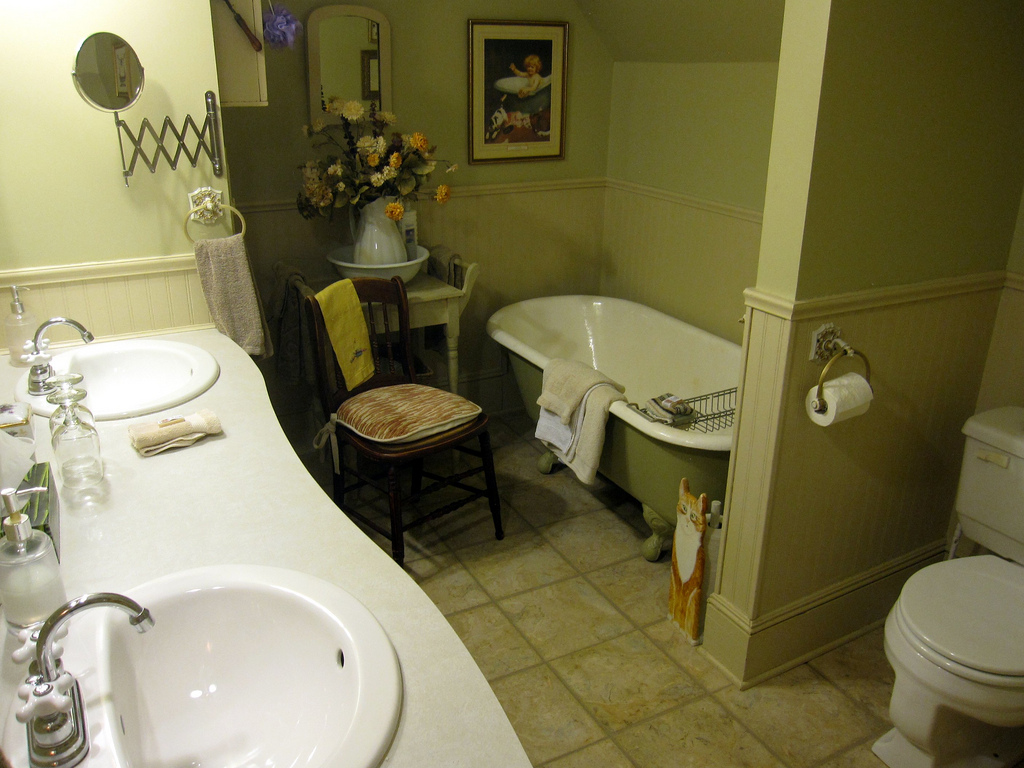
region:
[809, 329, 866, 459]
The hanging toilet paper roll.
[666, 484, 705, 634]
The wooden cat decor.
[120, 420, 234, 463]
The tan towel on the sink.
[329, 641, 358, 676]
The small drain hole.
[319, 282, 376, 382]
The yellow towel on the chair.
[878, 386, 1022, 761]
The white toilet bowl.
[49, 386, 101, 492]
The two glasses on the sink.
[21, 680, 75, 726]
The right knob on the faucet.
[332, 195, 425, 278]
The white glass vase.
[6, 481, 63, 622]
The glass soap dispenser.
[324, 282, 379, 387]
a yellow cloth on the brown chair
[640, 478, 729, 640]
it is a cat statue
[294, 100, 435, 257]
flowers in the vase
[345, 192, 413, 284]
a white vase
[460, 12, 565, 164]
framed art on the wall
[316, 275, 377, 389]
yellow towel on a chair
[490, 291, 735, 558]
claw foot bath tub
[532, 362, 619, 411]
small tan towel on a bath tub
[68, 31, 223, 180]
mirror extending from the wall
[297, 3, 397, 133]
mirror on the wall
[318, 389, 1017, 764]
tiled floor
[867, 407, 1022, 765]
a white porcelain toilet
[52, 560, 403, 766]
a white porcelain bathroom sink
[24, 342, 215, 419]
a white porcelain bathroom sink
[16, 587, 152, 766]
a chrome bathroom faucet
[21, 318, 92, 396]
a chrome bathroom faucet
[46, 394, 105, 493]
a clear drinking glass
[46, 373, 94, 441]
a clear drinking glass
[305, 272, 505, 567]
a brown wooden chair with pad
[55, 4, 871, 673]
the bathroom is spacious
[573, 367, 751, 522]
the bathtub is white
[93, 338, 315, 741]
these are sinks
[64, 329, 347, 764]
the sinks are white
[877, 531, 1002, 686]
this is a toilet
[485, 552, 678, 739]
the tiles are gray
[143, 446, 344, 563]
the counter top is white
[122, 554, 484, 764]
a white bathroom sink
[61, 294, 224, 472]
a white bathroom sink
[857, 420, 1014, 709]
a white bathroom toilet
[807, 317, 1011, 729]
a toilet is white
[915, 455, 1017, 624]
a white toilet in the bathroom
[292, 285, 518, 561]
A dark brown wooden chair with a cushion on it.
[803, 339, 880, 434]
A round metal toilet paper holder attached to the wall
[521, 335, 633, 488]
Towels hanging over the side of a bathtub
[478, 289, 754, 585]
A porcelain bathtub.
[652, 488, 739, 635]
A cat designed toilet paper holder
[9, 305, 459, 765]
A double bathroom sink.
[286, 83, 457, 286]
flowers in a large white pitcher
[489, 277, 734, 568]
a white porcelain tub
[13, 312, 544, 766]
a white porcelain double sink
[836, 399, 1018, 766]
a white porcelain toilet bowl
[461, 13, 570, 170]
a picture frame on the wall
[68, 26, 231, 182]
a mirror attach to a wall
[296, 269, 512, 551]
a brown chair with a cushion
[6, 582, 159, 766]
a silver sink faucet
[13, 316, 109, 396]
a silver sink faucet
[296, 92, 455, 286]
a bouquet of flowers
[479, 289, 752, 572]
white claw-foot bathtub with painted outside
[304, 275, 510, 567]
wooden chair with padded cushion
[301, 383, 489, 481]
padded cushion tied to wooden chair seat